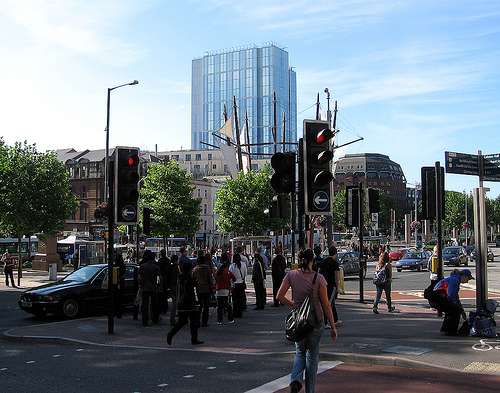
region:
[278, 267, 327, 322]
The brown shirt the girl is wearing.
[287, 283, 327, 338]
The black bag the girl in the brown shirt is wearing.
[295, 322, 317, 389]
The blue jeans the girl in the brown shirt is wearing.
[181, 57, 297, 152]
The tallest building in the distance.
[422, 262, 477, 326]
The lady kneeling down on the right.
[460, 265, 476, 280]
The blue hat the lady is wearing that is kneeling down on the right.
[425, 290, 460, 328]
The pants the lady kneeling down on the right is wearing.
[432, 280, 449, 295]
The red area on the lady's shirt that is kneeling down on the right.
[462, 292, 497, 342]
The bag on the ground that is next to the lady on the right that is kneeling down.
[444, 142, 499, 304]
The street sign and pole next to the lady that is kneeling down on the right.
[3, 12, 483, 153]
Mostly sunny with high elevation clouds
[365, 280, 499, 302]
Bike zone has red pavement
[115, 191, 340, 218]
Arrow signs are blue and white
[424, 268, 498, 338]
Person picking up items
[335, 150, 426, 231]
Interesting architectural building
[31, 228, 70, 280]
Monument in the square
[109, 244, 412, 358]
Everyone's back is towards the camera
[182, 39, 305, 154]
Sky scraper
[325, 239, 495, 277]
Cars waiting at red light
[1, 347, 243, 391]
White dotted lines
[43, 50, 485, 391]
a busy sidewalk in the city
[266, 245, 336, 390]
a woman carrying a black bag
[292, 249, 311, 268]
a brown ponytail on head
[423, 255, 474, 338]
a man picking up a bag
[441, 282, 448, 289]
a red patch on a blue jacket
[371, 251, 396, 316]
a girl wearing a black and white patterned backpack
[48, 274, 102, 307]
a car parked near the sidewalk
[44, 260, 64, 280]
a gray metal trash can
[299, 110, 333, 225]
a traffic light signaling on red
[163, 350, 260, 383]
white dotted lines in the street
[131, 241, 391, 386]
People crossing the street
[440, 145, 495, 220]
Guidepost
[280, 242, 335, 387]
Woman with shirt sleeved purple shirt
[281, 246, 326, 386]
Woman with jeans carrying large black bag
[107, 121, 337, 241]
The street lights are red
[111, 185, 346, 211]
The arrows point left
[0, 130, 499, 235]
Green leaves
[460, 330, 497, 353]
Bike zone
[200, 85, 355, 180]
Ships' masts sticking up behind trees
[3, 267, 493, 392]
Patches of sunshine and shade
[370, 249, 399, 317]
woman with backpac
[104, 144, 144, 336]
traffic light on the sidewalk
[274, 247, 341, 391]
woman holding black bag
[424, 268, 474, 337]
man wearing blue cap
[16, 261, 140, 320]
black car on the road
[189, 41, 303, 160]
building in the background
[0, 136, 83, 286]
tree on the sidewalk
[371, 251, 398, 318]
woman walking on the sidewalk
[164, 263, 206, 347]
woman wearing black pants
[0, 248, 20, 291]
persona standing on the sidewalk